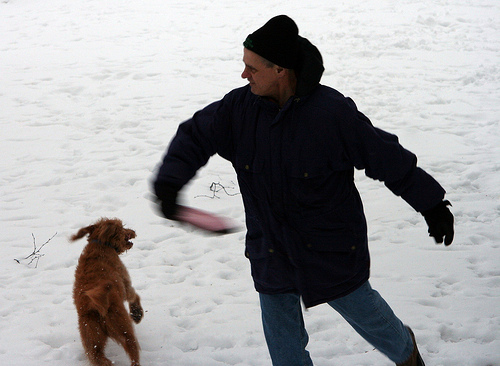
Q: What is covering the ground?
A: Snow.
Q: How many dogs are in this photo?
A: One.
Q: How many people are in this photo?
A: 1.